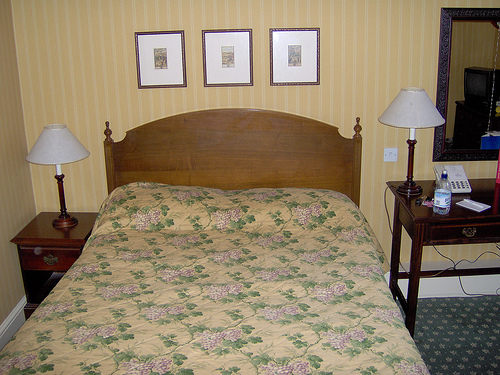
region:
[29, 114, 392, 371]
this is a bed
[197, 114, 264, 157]
the wood is brown in color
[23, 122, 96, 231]
this is a lamp shade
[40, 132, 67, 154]
the lamp shade is white in color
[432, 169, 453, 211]
this is a bottle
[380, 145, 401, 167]
this is a light switch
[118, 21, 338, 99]
these are several pictures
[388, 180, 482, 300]
this is a table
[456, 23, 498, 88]
this is a mirror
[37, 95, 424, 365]
queen size wood bed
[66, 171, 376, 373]
cover with pink flowers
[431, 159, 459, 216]
water bottle with sport top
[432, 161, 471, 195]
white telephone on desk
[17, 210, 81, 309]
wood night stand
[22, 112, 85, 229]
lamp with white shade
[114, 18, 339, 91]
three pictures on wall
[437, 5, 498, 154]
mirror hanging on the wall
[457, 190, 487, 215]
paper and pen on desk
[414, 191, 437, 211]
keys laying on desk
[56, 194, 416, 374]
floral pattern blanket is on bed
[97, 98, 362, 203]
headboard is brown wood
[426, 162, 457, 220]
clear plastic water bottle is on desk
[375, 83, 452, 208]
brown lamp with white shade is on desk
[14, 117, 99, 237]
brown lamp with white shade is on nightstand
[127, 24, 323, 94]
three framed pictures are above bed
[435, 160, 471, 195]
white phone is on brown desk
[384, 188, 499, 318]
brown desk has metal handle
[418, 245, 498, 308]
long cords are under desk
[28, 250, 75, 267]
brown nightstand has metal handle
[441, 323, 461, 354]
part of a floor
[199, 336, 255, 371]
part of a duvet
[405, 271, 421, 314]
part of a stand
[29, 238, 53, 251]
edge of a desktop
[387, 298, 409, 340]
edge of a bed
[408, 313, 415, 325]
part of a stand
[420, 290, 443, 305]
edge of a corner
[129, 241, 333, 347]
Floral print bedspread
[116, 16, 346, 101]
Three pictures hanging side by side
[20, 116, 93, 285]
Bedside lamp on nightstand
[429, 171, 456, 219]
Plastic bottle of water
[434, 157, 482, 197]
white landline telephone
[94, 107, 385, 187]
Wooden headboard of bed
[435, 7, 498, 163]
Large mirror hanging on the wall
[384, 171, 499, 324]
Dark wooden desk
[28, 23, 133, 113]
Wallpaper with vertical striped pattern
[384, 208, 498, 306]
Cords entangled under the desk